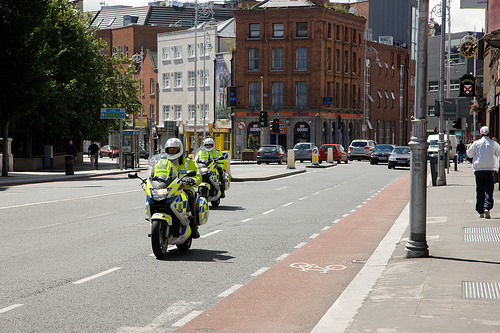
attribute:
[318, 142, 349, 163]
car — red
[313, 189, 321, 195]
line — white, painted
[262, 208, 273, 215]
line — white, painted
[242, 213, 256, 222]
line — white, painted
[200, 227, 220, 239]
line — white, painted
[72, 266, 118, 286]
line — white, painted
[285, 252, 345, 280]
indicator — bicycle lane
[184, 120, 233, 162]
storefront — yellow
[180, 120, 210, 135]
sign — white and red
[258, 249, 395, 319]
symbol — white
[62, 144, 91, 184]
trash can — black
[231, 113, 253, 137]
traffic sign — red, black, white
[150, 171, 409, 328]
bicycle lane — red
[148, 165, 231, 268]
motorcycles — yellow, blue & black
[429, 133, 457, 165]
van — white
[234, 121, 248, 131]
sign — no left turn 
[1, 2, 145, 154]
tree — large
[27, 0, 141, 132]
leaves — green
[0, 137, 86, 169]
wall — stone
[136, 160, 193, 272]
motorcycle — yellow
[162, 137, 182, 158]
helmet — white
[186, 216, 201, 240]
boots — black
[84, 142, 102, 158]
shirt — dark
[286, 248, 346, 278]
markings — bicycle lane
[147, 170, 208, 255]
motorcycle — neon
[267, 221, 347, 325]
lane — bike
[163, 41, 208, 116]
facade — white